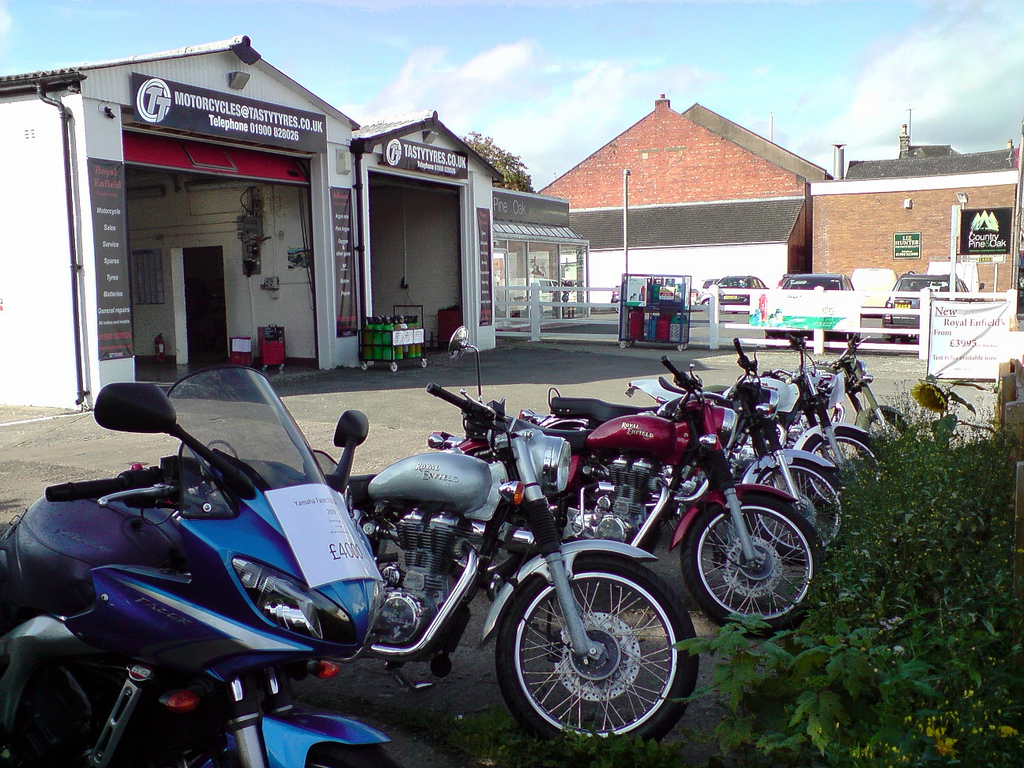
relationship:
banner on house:
[126, 70, 329, 160] [21, 40, 527, 386]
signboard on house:
[373, 127, 472, 188] [0, 26, 647, 377]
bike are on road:
[441, 357, 827, 636] [0, 365, 1013, 623]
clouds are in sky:
[394, 33, 1015, 126] [10, 1, 1014, 180]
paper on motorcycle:
[265, 477, 389, 589] [0, 367, 389, 766]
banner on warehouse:
[126, 70, 330, 160] [0, 32, 368, 388]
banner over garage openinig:
[126, 70, 329, 160] [122, 124, 316, 385]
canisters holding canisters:
[365, 310, 426, 361] [366, 310, 428, 361]